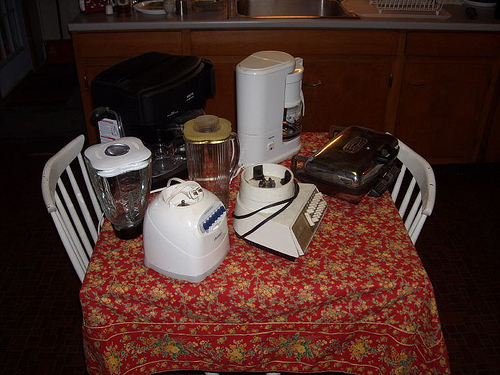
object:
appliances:
[83, 136, 153, 240]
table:
[79, 96, 454, 368]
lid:
[184, 115, 232, 145]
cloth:
[108, 134, 417, 309]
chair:
[39, 136, 105, 282]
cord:
[232, 198, 290, 219]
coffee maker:
[235, 51, 305, 168]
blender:
[184, 114, 232, 203]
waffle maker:
[291, 125, 401, 205]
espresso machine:
[91, 52, 214, 191]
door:
[74, 32, 494, 167]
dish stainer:
[375, 3, 446, 15]